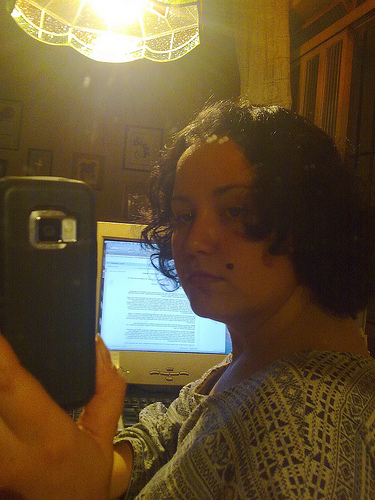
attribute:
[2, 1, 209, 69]
light — bright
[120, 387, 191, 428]
keyboard — black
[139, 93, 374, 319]
black hair — curly, wavy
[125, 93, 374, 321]
hair — black, curly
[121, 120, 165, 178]
picture — framed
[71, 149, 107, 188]
picture — framed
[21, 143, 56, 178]
picture — framed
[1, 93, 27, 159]
picture — framed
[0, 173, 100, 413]
phone — black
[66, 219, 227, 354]
computer screen — open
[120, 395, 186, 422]
keyboard — black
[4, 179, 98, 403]
camera — black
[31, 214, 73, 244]
camera eye — silver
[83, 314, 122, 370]
nail — clear